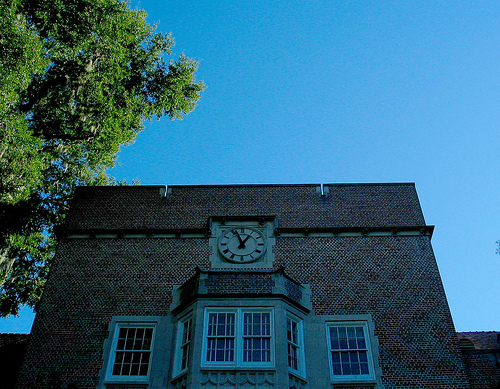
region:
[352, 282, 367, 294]
the building is made of brick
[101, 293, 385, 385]
the building has windows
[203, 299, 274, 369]
the window is big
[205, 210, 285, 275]
the clock is on the building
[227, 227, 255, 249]
the clock has hands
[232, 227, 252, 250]
the hands are black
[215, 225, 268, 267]
the clock is round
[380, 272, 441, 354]
the bricks are in triangular shape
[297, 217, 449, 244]
the building has a gutter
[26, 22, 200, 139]
the tree is taller then the building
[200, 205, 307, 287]
a small display of clock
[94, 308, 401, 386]
three windows of home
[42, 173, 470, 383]
a big old building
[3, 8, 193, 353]
a beautiful view of trees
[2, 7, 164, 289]
trees present on side of building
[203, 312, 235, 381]
iron rods in window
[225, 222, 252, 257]
hands of the clock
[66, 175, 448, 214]
top part of the building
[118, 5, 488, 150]
beautiful view of sky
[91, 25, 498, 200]
blue sky with no clouds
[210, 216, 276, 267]
CLOCK THAT TIME IS 12:55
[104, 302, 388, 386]
SIX DOUBLE HUNG WINDOWS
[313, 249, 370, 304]
DESIGN MADE OF BRICK ON BUILDING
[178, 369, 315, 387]
FANCY DESIGN UNDER WINDOWS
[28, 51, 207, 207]
GREEN TREE OVERHANGING BUILDING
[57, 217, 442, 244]
WOOD GUTTERING ON BUILDING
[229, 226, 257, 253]
BLACK METAL CLOCK HANDS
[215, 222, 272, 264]
ROMAN NUMERALS 1 THROUGH 12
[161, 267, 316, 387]
BRICK COVERED BAY WINDOW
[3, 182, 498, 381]
OLD BUILDING WITH CLOCK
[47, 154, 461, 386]
building with a clock on it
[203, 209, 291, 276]
clock indicating it's almost 1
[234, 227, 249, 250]
two black clock hands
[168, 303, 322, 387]
verandah with windows on it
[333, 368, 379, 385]
white window pane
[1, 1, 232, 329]
green tree top over the top of the building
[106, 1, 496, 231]
clear blue sky with no clouds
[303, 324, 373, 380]
window next to the verandah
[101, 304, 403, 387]
row of five windows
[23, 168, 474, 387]
dark building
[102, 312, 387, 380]
a row of windows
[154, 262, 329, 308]
a decorative stone balcony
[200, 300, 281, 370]
a pair of windows with white panes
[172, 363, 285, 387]
a row of decorative stone work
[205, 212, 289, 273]
a round, stone clock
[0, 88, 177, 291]
a tree with thick foliage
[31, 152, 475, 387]
a square brick building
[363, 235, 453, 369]
some decorative stone work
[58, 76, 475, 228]
a clear blue sky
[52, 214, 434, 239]
a decorative ledge